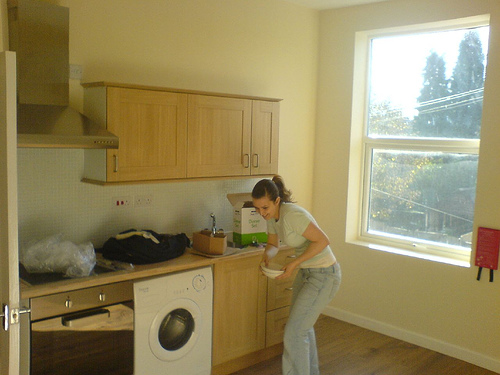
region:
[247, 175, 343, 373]
Woman holding white bowl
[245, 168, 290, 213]
Brown hair in ponytail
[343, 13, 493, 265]
Large window behind woman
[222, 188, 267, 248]
Green and white box next to faucet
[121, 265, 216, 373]
Washer next to dishwasher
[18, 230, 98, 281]
Plastic bag on top of dishwasher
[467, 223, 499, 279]
Red sign next to window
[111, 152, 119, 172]
Silver handle on cabinet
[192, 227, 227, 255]
Brown cardboard near faucet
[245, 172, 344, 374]
Woman wearing light blue jeans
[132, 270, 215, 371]
white built in washing machine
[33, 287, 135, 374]
stainless steel built in oven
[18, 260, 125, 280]
stainless steel stove top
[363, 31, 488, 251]
window in kitchen wall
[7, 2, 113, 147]
stainless steel exhaust hose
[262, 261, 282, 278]
white ceramic bowl in hand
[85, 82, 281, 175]
tan wood kitchen cabinets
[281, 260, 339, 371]
white wash denim jeans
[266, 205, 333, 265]
white cotton tee shirt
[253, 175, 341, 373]
girl standing in kitchen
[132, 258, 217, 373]
brand new washer/dryer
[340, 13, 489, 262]
very tall window looking out to back yard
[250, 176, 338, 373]
smiling woman in jeans carrying dishes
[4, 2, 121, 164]
large vent hood over stovetop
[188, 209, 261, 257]
sink piled with cardboard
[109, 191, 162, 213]
wall plates around switches and outlets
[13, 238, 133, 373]
stovetop and oven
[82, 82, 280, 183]
hanging wood cabinets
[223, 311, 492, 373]
hardwood flooring in a light stain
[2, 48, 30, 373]
edge of wooden door with metal handle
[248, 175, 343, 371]
Woman standing in the kitchen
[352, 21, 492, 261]
Large window in the kitchen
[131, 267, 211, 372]
Front of washing machine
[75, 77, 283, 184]
Tan colored cabinets over countertop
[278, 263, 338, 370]
Blue jeans woman is wearing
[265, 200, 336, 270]
White top woman is wearing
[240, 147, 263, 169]
Handles on front of upper cabinet doors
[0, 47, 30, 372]
White kitchen door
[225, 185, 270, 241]
White and green box on countertop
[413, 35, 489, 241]
Tall green trees through the window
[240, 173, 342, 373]
woman standing in the kitchen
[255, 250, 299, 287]
white bowl in the hands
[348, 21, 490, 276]
window with no blinds or curtains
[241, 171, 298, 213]
hair pulled back into a pony tail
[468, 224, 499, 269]
red box on the wall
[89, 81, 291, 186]
light brown cabinets on the wall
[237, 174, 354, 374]
woman hunched over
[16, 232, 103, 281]
plastic bags on the counter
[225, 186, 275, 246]
white and green box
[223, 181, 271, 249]
box that is open